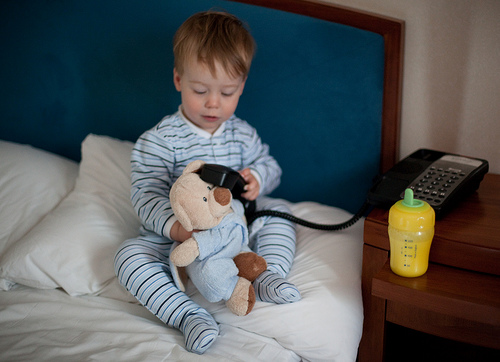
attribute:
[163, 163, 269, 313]
teddy bear — small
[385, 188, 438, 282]
juice cup — yellow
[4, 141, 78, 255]
pillow — white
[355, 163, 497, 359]
table — wooden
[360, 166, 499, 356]
nightstand — wooden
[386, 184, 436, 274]
cup — yellow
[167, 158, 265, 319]
stuffed animal — pictured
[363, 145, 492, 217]
phone — black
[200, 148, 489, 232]
phone — black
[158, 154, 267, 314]
teddy bear — brown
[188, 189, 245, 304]
outfit — blue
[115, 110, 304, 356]
pajamas — blue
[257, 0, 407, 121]
headboard — blue and brown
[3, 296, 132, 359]
sheet — white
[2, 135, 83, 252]
pillow — white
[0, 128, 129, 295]
pillow — white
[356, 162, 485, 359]
nightstand — dark brown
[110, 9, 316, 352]
boy — striped, young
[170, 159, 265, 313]
animal — stuffed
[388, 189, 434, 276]
cup — sippy, yellow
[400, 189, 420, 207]
top — lid, green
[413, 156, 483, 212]
keyboard — base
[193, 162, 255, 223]
telephone — black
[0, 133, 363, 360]
pillow — white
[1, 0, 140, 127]
background — blue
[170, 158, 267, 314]
bear — stufffed, stuffed